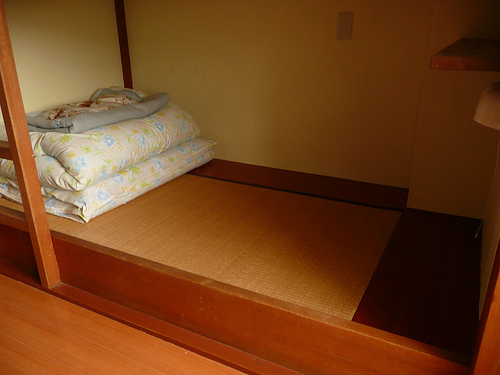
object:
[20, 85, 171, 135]
blanket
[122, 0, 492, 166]
wall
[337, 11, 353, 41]
socket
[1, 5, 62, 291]
ladder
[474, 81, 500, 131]
lamp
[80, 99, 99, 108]
flower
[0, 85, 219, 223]
comforter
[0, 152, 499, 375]
bed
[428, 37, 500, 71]
shelf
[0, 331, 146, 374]
floor